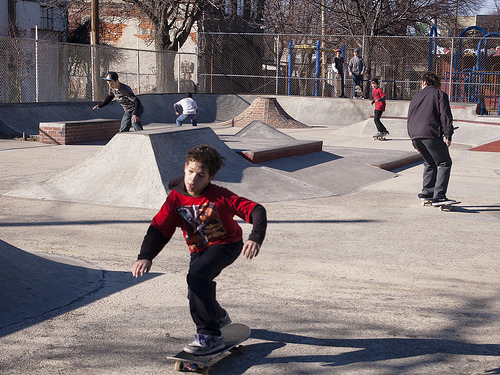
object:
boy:
[131, 144, 268, 355]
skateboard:
[165, 322, 251, 375]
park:
[0, 0, 500, 375]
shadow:
[207, 328, 500, 374]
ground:
[0, 116, 499, 375]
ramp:
[256, 149, 400, 195]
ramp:
[331, 116, 500, 149]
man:
[406, 72, 456, 207]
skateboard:
[422, 198, 462, 211]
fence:
[0, 24, 499, 116]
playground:
[205, 0, 499, 117]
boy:
[331, 49, 348, 99]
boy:
[347, 48, 366, 100]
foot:
[183, 333, 225, 355]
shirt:
[372, 86, 387, 111]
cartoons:
[177, 201, 228, 251]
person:
[92, 71, 144, 133]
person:
[173, 92, 199, 127]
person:
[370, 77, 388, 137]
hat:
[102, 71, 119, 81]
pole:
[287, 40, 294, 96]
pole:
[314, 40, 321, 97]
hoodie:
[136, 174, 267, 262]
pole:
[89, 0, 98, 102]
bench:
[37, 118, 121, 145]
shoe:
[183, 333, 226, 355]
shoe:
[216, 312, 233, 329]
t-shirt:
[176, 97, 199, 115]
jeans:
[175, 113, 197, 127]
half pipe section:
[218, 96, 311, 129]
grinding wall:
[235, 140, 325, 164]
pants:
[186, 238, 244, 337]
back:
[406, 84, 439, 139]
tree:
[122, 0, 212, 94]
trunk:
[155, 50, 178, 93]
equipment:
[443, 26, 500, 116]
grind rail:
[63, 119, 122, 144]